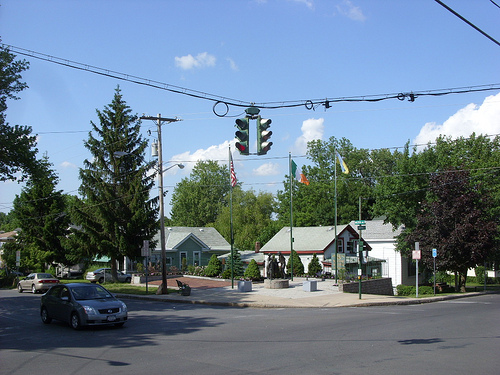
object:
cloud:
[172, 50, 238, 76]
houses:
[0, 215, 434, 286]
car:
[15, 272, 60, 293]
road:
[0, 291, 500, 373]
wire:
[0, 42, 499, 114]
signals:
[234, 118, 272, 153]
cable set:
[0, 43, 499, 118]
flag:
[230, 151, 237, 187]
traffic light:
[260, 119, 273, 155]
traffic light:
[235, 118, 248, 153]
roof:
[150, 226, 240, 252]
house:
[116, 226, 239, 275]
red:
[239, 144, 245, 152]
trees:
[170, 135, 497, 293]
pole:
[289, 153, 293, 281]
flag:
[292, 159, 297, 178]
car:
[40, 281, 128, 330]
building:
[145, 227, 235, 272]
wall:
[178, 238, 203, 272]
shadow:
[0, 284, 259, 368]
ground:
[0, 288, 499, 375]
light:
[239, 144, 246, 151]